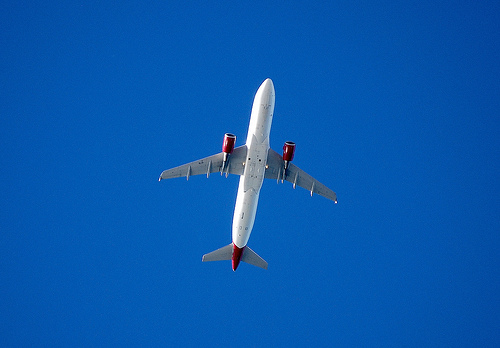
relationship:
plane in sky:
[150, 49, 355, 280] [0, 2, 497, 346]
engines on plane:
[212, 127, 301, 163] [150, 49, 355, 280]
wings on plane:
[145, 134, 342, 210] [150, 49, 355, 280]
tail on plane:
[196, 234, 282, 274] [150, 49, 355, 280]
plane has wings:
[150, 49, 355, 280] [145, 134, 342, 210]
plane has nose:
[150, 49, 355, 280] [256, 72, 275, 97]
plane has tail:
[150, 49, 355, 280] [196, 234, 282, 274]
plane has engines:
[150, 49, 355, 280] [212, 127, 301, 163]